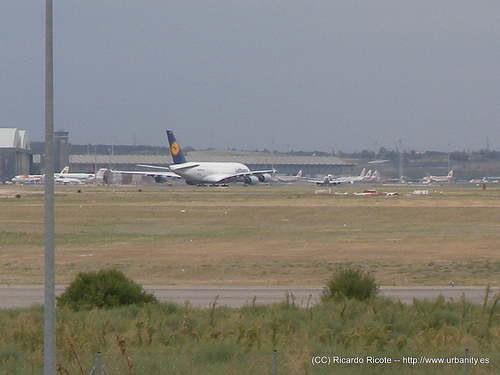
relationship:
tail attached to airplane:
[164, 129, 187, 166] [122, 133, 285, 190]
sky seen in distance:
[2, 1, 483, 153] [2, 1, 483, 178]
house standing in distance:
[420, 149, 428, 153] [2, 1, 483, 178]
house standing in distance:
[414, 150, 420, 154] [2, 1, 483, 178]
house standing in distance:
[468, 152, 484, 161] [2, 1, 483, 178]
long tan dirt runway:
[3, 250, 493, 309] [91, 270, 494, 287]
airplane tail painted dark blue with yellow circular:
[154, 83, 203, 153] [153, 99, 213, 222]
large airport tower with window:
[64, 214, 352, 328] [18, 148, 106, 243]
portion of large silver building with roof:
[6, 117, 90, 201] [17, 161, 333, 222]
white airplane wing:
[107, 99, 176, 182] [83, 124, 188, 231]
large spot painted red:
[364, 169, 403, 204] [318, 165, 414, 259]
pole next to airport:
[32, 195, 79, 375] [41, 178, 492, 338]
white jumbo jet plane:
[109, 146, 319, 296] [104, 124, 306, 225]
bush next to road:
[58, 255, 156, 314] [4, 266, 478, 315]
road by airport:
[4, 234, 479, 371] [41, 178, 492, 338]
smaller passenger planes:
[4, 163, 152, 253] [7, 121, 175, 291]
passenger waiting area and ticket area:
[57, 165, 471, 298] [64, 167, 437, 301]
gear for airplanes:
[54, 136, 477, 298] [272, 134, 467, 224]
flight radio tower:
[300, 94, 456, 223] [304, 100, 484, 250]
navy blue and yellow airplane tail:
[137, 108, 219, 243] [164, 129, 187, 166]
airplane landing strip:
[122, 133, 285, 190] [32, 261, 432, 374]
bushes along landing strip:
[74, 290, 498, 375] [32, 261, 432, 374]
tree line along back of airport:
[55, 144, 470, 163] [1, 100, 474, 213]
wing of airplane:
[205, 169, 278, 182] [122, 133, 285, 190]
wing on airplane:
[205, 169, 278, 182] [122, 133, 285, 190]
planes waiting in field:
[271, 167, 463, 190] [38, 164, 479, 274]